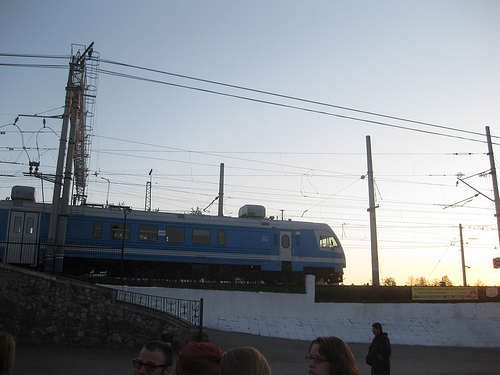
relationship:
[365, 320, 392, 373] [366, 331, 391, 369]
man in clothing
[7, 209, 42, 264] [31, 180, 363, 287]
train door on side of train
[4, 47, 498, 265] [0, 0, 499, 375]
wires in air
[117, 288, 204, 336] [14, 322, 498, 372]
fence along walkway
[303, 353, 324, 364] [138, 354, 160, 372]
glasses on face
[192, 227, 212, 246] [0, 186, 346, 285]
window on train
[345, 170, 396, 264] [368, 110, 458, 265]
pole supporting polewires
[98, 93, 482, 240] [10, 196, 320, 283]
wires above train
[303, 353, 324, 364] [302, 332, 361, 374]
glasses on woman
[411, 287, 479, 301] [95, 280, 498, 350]
sign on wall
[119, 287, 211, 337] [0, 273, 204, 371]
fence by a train stop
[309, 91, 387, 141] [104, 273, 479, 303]
power lines beside track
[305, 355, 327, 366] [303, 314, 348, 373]
glasses on face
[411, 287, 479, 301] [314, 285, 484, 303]
sign on concrete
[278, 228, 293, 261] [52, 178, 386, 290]
door on train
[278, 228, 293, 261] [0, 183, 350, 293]
door on train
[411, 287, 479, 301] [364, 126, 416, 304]
sign on wall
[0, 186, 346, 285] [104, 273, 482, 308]
train on track